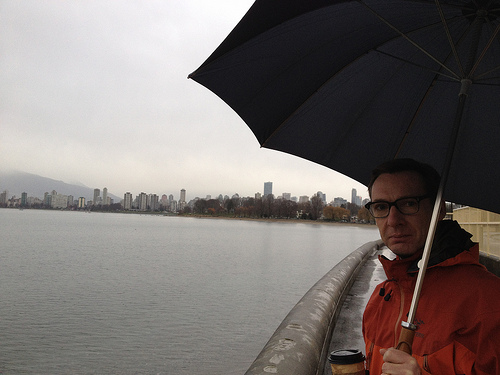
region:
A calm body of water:
[16, 213, 258, 373]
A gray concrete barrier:
[256, 295, 328, 373]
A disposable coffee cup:
[315, 340, 375, 373]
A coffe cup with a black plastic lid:
[322, 341, 369, 373]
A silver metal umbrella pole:
[395, 177, 445, 333]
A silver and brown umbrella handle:
[395, 317, 418, 367]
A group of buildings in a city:
[111, 186, 201, 218]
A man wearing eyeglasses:
[342, 155, 482, 284]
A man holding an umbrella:
[197, 108, 495, 373]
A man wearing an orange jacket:
[304, 143, 496, 370]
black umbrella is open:
[187, 0, 497, 212]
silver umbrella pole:
[401, 76, 468, 331]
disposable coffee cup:
[327, 350, 366, 371]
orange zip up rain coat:
[360, 246, 498, 369]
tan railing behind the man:
[452, 208, 498, 253]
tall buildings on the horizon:
[0, 182, 364, 219]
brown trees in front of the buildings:
[172, 203, 366, 223]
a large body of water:
[5, 213, 374, 373]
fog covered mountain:
[0, 162, 116, 210]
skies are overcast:
[0, 5, 351, 190]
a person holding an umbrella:
[192, 70, 494, 354]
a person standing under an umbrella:
[195, 69, 489, 365]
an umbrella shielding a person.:
[188, 71, 476, 235]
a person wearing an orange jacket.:
[362, 245, 495, 372]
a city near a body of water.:
[61, 178, 261, 263]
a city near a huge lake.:
[85, 180, 262, 253]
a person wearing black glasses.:
[356, 191, 433, 236]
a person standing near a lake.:
[354, 169, 479, 369]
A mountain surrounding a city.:
[12, 160, 100, 226]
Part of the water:
[58, 249, 150, 334]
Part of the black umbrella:
[290, 43, 360, 97]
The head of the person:
[360, 155, 458, 262]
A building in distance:
[121, 188, 136, 212]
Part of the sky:
[61, 62, 131, 136]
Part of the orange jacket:
[443, 300, 476, 341]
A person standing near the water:
[329, 145, 498, 372]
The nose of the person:
[384, 200, 404, 230]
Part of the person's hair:
[388, 158, 404, 170]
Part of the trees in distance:
[250, 195, 263, 207]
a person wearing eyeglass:
[359, 192, 432, 222]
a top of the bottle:
[328, 338, 373, 368]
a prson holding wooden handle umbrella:
[389, 320, 428, 370]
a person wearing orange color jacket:
[353, 256, 498, 370]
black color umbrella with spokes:
[257, 7, 495, 159]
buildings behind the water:
[82, 183, 314, 213]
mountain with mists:
[11, 168, 90, 193]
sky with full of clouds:
[21, 29, 176, 165]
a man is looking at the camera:
[358, 168, 463, 263]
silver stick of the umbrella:
[440, 108, 464, 186]